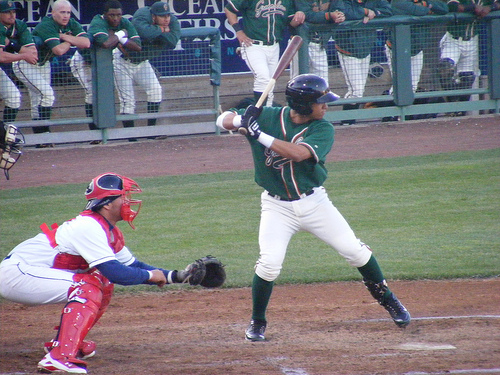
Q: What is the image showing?
A: It is showing a field.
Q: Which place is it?
A: It is a field.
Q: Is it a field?
A: Yes, it is a field.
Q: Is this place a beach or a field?
A: It is a field.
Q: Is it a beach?
A: No, it is a field.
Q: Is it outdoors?
A: Yes, it is outdoors.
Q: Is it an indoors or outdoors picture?
A: It is outdoors.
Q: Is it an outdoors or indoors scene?
A: It is outdoors.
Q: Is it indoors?
A: No, it is outdoors.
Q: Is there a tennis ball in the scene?
A: No, there are no tennis balls.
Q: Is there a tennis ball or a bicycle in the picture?
A: No, there are no tennis balls or bicycles.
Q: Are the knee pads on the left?
A: Yes, the knee pads are on the left of the image.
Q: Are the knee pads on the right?
A: No, the knee pads are on the left of the image.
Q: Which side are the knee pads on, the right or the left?
A: The knee pads are on the left of the image.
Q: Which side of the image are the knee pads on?
A: The knee pads are on the left of the image.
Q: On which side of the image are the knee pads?
A: The knee pads are on the left of the image.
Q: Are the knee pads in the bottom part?
A: Yes, the knee pads are in the bottom of the image.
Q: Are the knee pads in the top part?
A: No, the knee pads are in the bottom of the image.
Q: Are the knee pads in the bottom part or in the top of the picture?
A: The knee pads are in the bottom of the image.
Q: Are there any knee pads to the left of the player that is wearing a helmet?
A: Yes, there are knee pads to the left of the player.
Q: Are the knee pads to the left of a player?
A: Yes, the knee pads are to the left of a player.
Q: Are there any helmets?
A: Yes, there is a helmet.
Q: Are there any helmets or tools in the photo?
A: Yes, there is a helmet.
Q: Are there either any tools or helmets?
A: Yes, there is a helmet.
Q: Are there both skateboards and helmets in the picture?
A: No, there is a helmet but no skateboards.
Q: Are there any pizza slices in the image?
A: No, there are no pizza slices.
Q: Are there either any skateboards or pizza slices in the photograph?
A: No, there are no pizza slices or skateboards.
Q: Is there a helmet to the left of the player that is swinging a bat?
A: Yes, there is a helmet to the left of the player.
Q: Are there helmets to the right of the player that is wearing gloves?
A: No, the helmet is to the left of the player.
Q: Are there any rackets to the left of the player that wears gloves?
A: No, there is a helmet to the left of the player.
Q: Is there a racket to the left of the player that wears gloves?
A: No, there is a helmet to the left of the player.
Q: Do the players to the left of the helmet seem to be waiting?
A: Yes, the players are waiting.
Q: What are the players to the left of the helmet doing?
A: The players are waiting.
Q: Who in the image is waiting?
A: The players are waiting.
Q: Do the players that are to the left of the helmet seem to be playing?
A: No, the players are waiting.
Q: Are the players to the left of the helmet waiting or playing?
A: The players are waiting.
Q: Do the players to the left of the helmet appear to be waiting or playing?
A: The players are waiting.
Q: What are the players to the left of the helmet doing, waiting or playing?
A: The players are waiting.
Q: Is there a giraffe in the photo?
A: No, there are no giraffes.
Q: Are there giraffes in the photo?
A: No, there are no giraffes.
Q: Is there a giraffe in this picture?
A: No, there are no giraffes.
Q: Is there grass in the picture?
A: Yes, there is grass.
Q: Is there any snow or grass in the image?
A: Yes, there is grass.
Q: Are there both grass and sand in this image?
A: No, there is grass but no sand.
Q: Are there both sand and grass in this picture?
A: No, there is grass but no sand.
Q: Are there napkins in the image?
A: No, there are no napkins.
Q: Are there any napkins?
A: No, there are no napkins.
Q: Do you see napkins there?
A: No, there are no napkins.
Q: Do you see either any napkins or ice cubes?
A: No, there are no napkins or ice cubes.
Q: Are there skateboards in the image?
A: No, there are no skateboards.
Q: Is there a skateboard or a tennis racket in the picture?
A: No, there are no skateboards or rackets.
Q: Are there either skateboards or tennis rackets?
A: No, there are no skateboards or tennis rackets.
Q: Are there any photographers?
A: No, there are no photographers.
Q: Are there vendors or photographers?
A: No, there are no photographers or vendors.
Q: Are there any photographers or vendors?
A: No, there are no photographers or vendors.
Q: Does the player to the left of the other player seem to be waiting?
A: Yes, the player is waiting.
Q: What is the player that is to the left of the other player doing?
A: The player is waiting.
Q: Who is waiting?
A: The player is waiting.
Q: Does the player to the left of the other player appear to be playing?
A: No, the player is waiting.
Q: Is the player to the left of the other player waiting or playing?
A: The player is waiting.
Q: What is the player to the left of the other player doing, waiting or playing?
A: The player is waiting.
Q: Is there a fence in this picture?
A: Yes, there is a fence.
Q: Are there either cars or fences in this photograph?
A: Yes, there is a fence.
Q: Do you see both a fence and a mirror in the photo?
A: No, there is a fence but no mirrors.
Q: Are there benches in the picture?
A: No, there are no benches.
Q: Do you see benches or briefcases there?
A: No, there are no benches or briefcases.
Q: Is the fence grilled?
A: Yes, the fence is grilled.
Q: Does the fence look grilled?
A: Yes, the fence is grilled.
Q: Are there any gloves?
A: Yes, there are gloves.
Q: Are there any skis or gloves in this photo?
A: Yes, there are gloves.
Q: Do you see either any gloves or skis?
A: Yes, there are gloves.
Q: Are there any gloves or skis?
A: Yes, there are gloves.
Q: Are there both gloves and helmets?
A: Yes, there are both gloves and a helmet.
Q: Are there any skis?
A: No, there are no skis.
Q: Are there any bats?
A: Yes, there is a bat.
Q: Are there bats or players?
A: Yes, there is a bat.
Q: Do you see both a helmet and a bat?
A: Yes, there are both a bat and a helmet.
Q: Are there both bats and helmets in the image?
A: Yes, there are both a bat and a helmet.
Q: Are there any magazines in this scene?
A: No, there are no magazines.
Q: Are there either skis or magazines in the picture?
A: No, there are no magazines or skis.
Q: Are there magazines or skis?
A: No, there are no magazines or skis.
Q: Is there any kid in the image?
A: No, there are no children.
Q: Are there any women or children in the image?
A: No, there are no children or women.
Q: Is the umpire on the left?
A: Yes, the umpire is on the left of the image.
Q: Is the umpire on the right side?
A: No, the umpire is on the left of the image.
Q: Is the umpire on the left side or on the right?
A: The umpire is on the left of the image.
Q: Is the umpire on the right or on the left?
A: The umpire is on the left of the image.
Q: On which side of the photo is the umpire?
A: The umpire is on the left of the image.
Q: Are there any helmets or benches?
A: Yes, there is a helmet.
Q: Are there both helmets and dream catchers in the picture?
A: No, there is a helmet but no dream catchers.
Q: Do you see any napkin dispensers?
A: No, there are no napkin dispensers.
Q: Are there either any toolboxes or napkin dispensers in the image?
A: No, there are no napkin dispensers or toolboxes.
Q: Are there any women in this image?
A: No, there are no women.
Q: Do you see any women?
A: No, there are no women.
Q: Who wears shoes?
A: The player wears shoes.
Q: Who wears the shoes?
A: The player wears shoes.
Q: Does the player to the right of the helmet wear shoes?
A: Yes, the player wears shoes.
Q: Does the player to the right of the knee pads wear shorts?
A: No, the player wears shoes.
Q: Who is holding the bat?
A: The player is holding the bat.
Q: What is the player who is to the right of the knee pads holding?
A: The player is holding the bat.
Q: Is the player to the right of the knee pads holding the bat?
A: Yes, the player is holding the bat.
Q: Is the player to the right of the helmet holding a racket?
A: No, the player is holding the bat.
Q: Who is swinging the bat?
A: The player is swinging the bat.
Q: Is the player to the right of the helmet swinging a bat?
A: Yes, the player is swinging a bat.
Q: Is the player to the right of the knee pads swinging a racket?
A: No, the player is swinging a bat.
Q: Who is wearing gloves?
A: The player is wearing gloves.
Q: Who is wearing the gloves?
A: The player is wearing gloves.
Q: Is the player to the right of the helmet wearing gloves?
A: Yes, the player is wearing gloves.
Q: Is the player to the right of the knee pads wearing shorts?
A: No, the player is wearing gloves.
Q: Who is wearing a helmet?
A: The player is wearing a helmet.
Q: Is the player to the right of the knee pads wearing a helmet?
A: Yes, the player is wearing a helmet.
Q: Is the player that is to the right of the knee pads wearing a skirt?
A: No, the player is wearing a helmet.